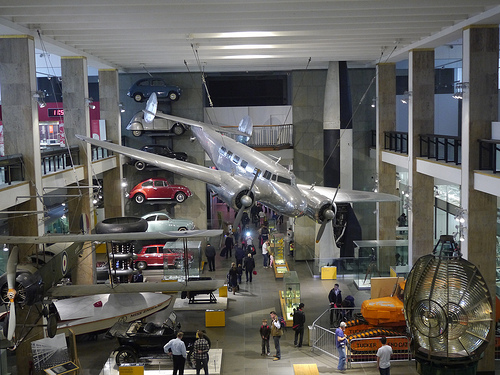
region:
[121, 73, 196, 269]
Volkswagons hanging on the wall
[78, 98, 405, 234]
silver airplane hanging from the ceiling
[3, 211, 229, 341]
bi-plane hanging on the left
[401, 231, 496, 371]
light house light on display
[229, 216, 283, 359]
people enjoying the exhibit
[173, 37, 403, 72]
wire attached to the ceiling to support plane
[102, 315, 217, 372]
two people looking at an old car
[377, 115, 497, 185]
second floor observation area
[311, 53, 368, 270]
rocket in corner going thru ceiling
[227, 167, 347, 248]
propellers of silver plane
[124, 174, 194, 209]
A red VW Bug on a wall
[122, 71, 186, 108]
A blue car on a wall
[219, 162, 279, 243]
The right propeller of a plane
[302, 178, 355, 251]
The left propeller of a plane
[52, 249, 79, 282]
A red, white and blue circle on a plane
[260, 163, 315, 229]
The cockpit of a twin engine plane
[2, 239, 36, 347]
The propeller of an old plane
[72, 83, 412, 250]
A plane hanging from the inside of a building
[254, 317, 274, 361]
A boy in a blue jacket standing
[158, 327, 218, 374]
Two people standing by an old car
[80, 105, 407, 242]
a silver plane on the ceiling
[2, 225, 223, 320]
a double wing plane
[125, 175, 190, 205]
a red car on a wall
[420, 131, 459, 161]
a black metal railing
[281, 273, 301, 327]
a clear display cases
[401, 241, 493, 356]
a larger silver fan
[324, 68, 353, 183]
a black and white color wall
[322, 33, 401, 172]
a metal cable from the ceiling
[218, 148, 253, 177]
side windows on a plane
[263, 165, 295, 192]
front windshield on a plane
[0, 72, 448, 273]
plane hanging from ceiling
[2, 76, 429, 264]
the plane is gray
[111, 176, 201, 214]
the car is red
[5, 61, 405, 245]
plane is hanging sideways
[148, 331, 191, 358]
man's shirt is white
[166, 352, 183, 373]
man's pants are black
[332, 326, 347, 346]
man's shirt is blue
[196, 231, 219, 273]
man standing near red car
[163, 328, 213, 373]
2 men are talking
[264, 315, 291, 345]
person's shirt is brown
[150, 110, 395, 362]
this is a museum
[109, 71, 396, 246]
this is a plane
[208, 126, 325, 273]
the plane is silver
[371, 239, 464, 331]
this is a fan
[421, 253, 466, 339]
the fan is black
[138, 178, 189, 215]
this is a car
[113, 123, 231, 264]
the car is red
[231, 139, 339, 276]
this is the front of the plane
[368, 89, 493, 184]
this is a platform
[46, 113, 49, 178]
this is a bar